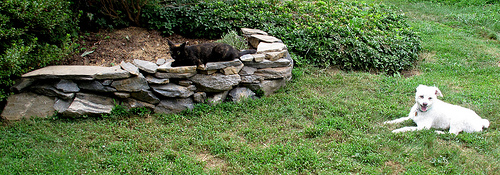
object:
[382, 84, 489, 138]
dog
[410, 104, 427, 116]
collar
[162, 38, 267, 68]
cat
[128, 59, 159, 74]
rocks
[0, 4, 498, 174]
grass